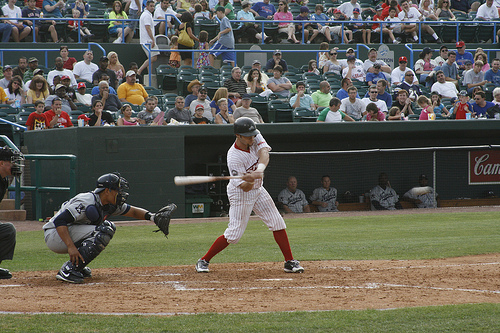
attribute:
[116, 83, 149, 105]
shirt — bright, orange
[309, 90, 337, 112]
shirt — lime, green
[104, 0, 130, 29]
person — yellow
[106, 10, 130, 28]
shirt — florescent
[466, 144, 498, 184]
advertisement — edge, coca, cola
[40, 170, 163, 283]
man — crouched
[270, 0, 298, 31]
woman — pink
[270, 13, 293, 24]
blouse — dark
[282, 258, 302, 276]
shoe — man's, tennis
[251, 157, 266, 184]
wristband — white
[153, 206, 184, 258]
baseball glove — black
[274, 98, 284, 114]
stadium seat — green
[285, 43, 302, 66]
pole — blue, long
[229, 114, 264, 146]
baseball hat — black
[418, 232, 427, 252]
grass — green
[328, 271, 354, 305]
line — white, long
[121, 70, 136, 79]
baseball cap — tan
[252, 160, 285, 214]
wristband — white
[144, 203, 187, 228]
baseball glove — black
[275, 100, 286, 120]
stadium seat — green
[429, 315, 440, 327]
grass — green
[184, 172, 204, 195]
baseball bat — brown, white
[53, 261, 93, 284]
tennis shoe — man's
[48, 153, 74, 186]
stair rail — green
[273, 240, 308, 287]
sock — long, red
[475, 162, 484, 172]
capital letter — white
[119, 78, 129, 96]
man — large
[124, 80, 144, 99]
shirt — orange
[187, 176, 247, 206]
baseball bat — white, horizontal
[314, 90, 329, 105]
shirt — lime green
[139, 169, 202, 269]
mitt — black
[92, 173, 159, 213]
facemask — black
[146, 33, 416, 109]
seats — green